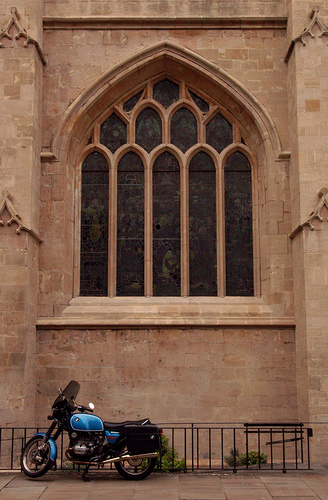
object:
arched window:
[49, 41, 282, 326]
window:
[224, 153, 252, 297]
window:
[206, 114, 233, 156]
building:
[0, 0, 327, 470]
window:
[151, 152, 180, 297]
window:
[80, 149, 107, 298]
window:
[169, 105, 196, 157]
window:
[132, 106, 163, 153]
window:
[99, 113, 126, 157]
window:
[151, 79, 177, 111]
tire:
[18, 429, 58, 478]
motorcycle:
[18, 381, 164, 480]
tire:
[110, 436, 158, 481]